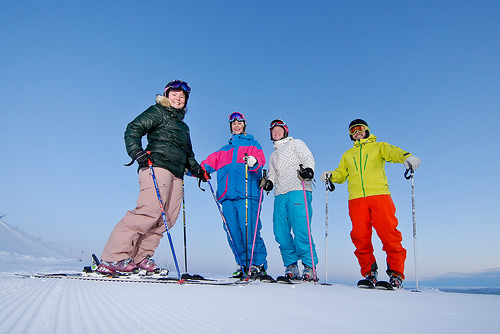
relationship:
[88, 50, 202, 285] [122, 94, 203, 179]
woman in black coat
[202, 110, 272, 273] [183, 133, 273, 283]
woman in ski suit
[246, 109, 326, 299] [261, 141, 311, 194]
woman wearing a jacket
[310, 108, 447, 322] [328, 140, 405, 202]
woman wearing a jacket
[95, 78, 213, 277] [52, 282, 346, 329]
woman on snow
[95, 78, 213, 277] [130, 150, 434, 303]
woman holding ski sticks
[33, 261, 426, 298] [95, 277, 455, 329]
ski boards on snow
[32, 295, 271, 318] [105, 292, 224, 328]
snow on ground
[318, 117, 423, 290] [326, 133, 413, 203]
woman in snow coat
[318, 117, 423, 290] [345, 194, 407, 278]
woman in snow pants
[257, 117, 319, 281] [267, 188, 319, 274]
woman in snow pants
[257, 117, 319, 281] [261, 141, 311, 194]
woman in jacket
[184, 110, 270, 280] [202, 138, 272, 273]
woman in ski outfit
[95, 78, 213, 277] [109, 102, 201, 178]
woman in jacket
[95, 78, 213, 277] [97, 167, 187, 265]
woman in snow pants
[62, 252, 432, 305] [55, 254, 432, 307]
sets of skies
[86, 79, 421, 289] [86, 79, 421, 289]
four people of four people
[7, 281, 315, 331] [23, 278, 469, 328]
clean/white snow on ground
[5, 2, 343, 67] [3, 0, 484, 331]
clear/blue sky in top of picture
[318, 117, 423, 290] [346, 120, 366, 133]
woman wearing ski goggles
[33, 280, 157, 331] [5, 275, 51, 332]
ground snow has tracks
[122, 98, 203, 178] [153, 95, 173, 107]
black coat with fur trim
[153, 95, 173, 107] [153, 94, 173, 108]
fur trim by fur trim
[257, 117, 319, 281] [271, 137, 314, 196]
woman wearing only a turtleneck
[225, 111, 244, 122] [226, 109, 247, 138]
blue/ski goggles on woman's forehead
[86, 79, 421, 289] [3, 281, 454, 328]
four people on ski slope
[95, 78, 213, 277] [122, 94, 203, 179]
woman wearing black coat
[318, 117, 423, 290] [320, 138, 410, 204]
woman wearing snow coat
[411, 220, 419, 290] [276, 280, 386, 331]
skis on snow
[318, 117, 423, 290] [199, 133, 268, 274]
woman wearing a ski outfit